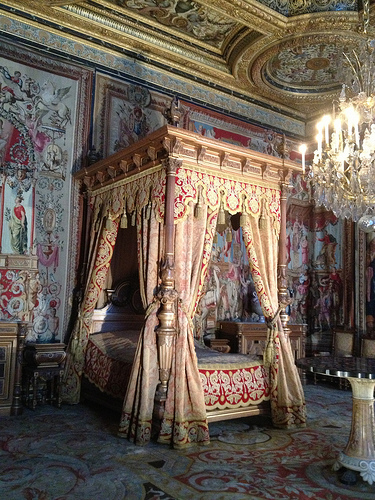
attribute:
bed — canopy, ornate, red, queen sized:
[63, 123, 308, 440]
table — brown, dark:
[14, 322, 68, 400]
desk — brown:
[1, 318, 35, 409]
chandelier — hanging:
[304, 78, 374, 204]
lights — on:
[302, 112, 362, 142]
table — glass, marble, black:
[304, 321, 374, 468]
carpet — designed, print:
[216, 460, 287, 500]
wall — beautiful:
[11, 54, 100, 150]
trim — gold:
[183, 28, 216, 79]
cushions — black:
[323, 328, 355, 358]